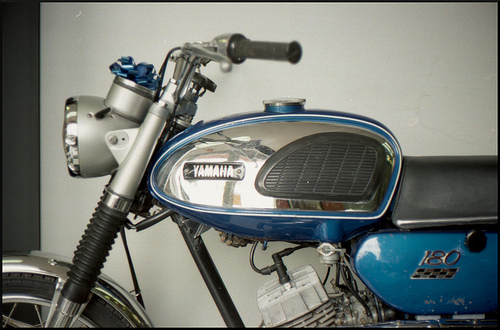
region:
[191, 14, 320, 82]
black handlebars on bike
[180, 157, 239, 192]
black and silver logo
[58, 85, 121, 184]
silver and chrome headlight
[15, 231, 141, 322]
chrome cover for wheel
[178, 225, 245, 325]
black frame bar on bike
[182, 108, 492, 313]
blue and chrome frame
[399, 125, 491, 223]
black seat on bike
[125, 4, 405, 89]
white wall behind bike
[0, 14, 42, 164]
black wall near white wall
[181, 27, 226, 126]
steel bars near handles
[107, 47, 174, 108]
the bow is blue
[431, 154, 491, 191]
the seat is black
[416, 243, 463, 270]
the number is silver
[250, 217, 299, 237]
the tank is blue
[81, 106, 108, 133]
the light case is gray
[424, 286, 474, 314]
some of the paint is chipping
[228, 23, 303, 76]
the handle is black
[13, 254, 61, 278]
the fender is silver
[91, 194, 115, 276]
the shock cover is black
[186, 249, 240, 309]
the pipe is black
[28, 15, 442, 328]
a motorcycle inside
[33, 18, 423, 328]
a motorcycle with a bow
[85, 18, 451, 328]
a yamaha motorcycle inside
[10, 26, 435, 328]
a blue motorcycle inside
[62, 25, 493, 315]
a blue motorcycle with a blue bow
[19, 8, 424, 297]
a bow on a blue motorcycle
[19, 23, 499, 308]
a bow on a yamaha motorcycle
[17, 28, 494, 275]
a bow on a blue yamaha motorcycle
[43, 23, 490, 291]
an old style motorcycle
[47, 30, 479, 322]
an old style bike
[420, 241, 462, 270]
chrome 180 on blue painted motorcycle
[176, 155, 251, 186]
chrome Yamaha logo on chrome part of bike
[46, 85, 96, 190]
headlight with chrome around it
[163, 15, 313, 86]
chrome handlebar with black plastic grip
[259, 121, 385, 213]
vent detail on chrome gas tank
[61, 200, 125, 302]
black plastic detailing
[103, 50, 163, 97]
blue gift bow on blue painted bike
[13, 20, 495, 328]
blue painted yamaha motorcycle with chrome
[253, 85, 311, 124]
chrome cap on blue and chrome gas tank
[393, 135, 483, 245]
black leather seat on motorcycle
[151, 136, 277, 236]
reflection on motorcycle chrome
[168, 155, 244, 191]
makers name on 'cycle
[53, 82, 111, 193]
head light of 'cycle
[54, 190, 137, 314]
shock of the 'cycle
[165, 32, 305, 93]
handle bar of 'cycle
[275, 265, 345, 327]
top of motor of the vehicle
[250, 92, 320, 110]
lid of the tank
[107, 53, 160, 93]
bow on the vehicle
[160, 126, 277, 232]
light from the window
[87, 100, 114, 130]
switch on the headlight